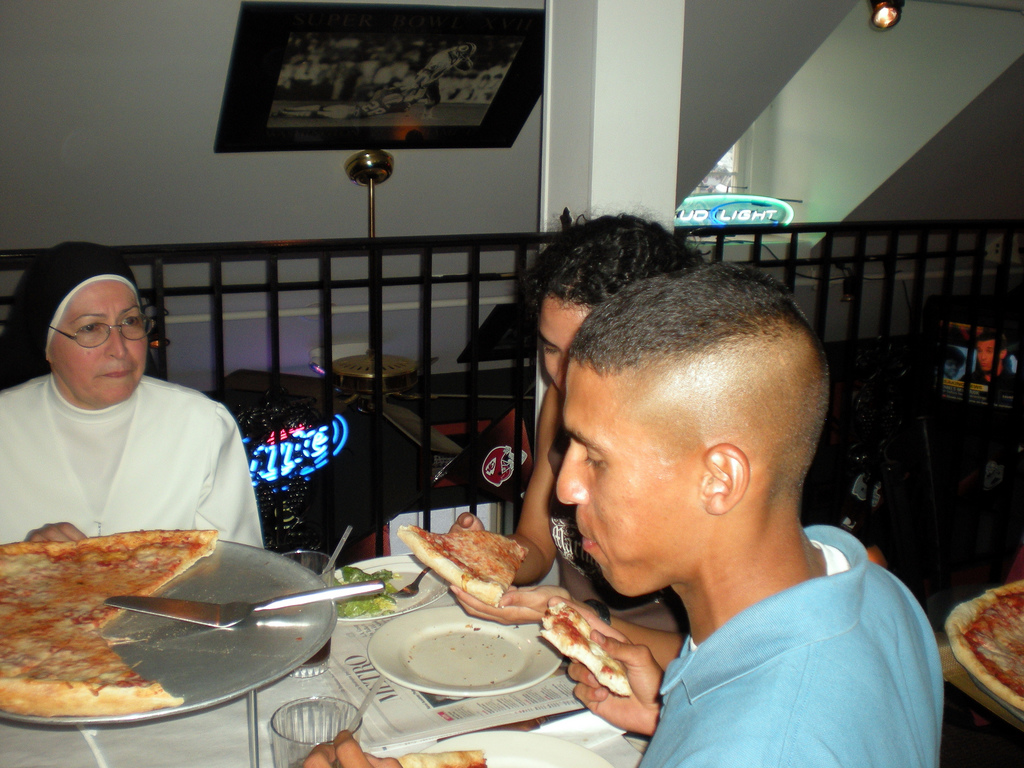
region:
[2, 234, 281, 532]
nun in the habit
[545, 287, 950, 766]
boy with the blue polo shirt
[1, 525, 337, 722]
pizza that is half eaten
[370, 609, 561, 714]
plate that is empty besides crumbs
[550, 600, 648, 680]
half eaten pizza in the front boys hands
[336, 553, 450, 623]
plate with the salad on it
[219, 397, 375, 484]
miller lite neon sign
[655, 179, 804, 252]
bid light neon light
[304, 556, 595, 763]
paper on the table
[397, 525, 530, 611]
a slice of cheese pizza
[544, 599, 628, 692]
a slice of cheese pizza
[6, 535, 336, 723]
a partially eaten whole pizza pie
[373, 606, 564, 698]
a white dinner plate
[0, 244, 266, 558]
a seated Catholic Nun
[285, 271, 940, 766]
a young man eating pizza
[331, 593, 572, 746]
a folded newspaper on table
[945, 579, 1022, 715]
a cheese pizza pie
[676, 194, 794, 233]
a Bud Light neon sign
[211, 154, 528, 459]
a overhead ceiling fan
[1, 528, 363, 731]
pizza on the metal sheet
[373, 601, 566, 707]
plate that is empty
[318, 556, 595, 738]
newspaper section with metro on it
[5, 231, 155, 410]
nun's head and habit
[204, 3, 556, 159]
black and white picture on the wall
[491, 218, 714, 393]
person that is mostly covered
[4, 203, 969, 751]
the people are eating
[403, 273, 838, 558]
man is looking down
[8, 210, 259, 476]
the woman is wearing glasses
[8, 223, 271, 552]
the woman is a nun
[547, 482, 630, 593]
the mouth is closed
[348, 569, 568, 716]
the plate is white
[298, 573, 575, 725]
a newspaper is under the plate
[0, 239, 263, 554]
woman wearing a black veil and a white robe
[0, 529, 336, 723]
a half-eaten pizza sitting on a silver plate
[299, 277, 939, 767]
man with short hair eating a pizza slice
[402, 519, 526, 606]
a pizza slice with tomato sauce and cheese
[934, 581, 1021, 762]
a whole pizza sitting on a wooden table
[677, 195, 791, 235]
a neon blue sign with white lettering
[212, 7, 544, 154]
a picture in a black frame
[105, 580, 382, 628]
a shinny silvery pizza serving spatula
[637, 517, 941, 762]
a white shirt underneath a blue shirt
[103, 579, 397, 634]
silver metal pizza server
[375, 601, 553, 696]
round white plate on table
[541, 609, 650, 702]
hand holding pizza slice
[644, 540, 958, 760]
bright blue polo shirt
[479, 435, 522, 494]
red and white sticker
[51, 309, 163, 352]
thin brown framed glasses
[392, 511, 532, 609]
hands holding pizza slice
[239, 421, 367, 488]
blue lighted sign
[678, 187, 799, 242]
blue lighted sign on wall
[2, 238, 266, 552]
a nun sitting at the table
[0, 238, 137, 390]
black head covering the nun is wearing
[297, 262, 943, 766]
young man in a blue shirt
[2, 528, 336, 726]
pizza a the round metal platter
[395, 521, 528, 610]
slice of pizza the girl is holding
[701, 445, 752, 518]
the young man's left ear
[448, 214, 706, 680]
black-haired girl holding a pizza slice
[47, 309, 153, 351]
eyeglasses the nun is wearing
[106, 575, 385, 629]
metal pizza server next ot the pizza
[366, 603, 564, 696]
empty white plate on the table